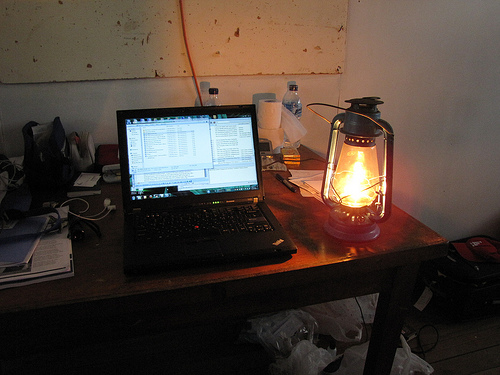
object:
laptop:
[112, 102, 299, 274]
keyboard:
[131, 200, 278, 246]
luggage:
[415, 231, 499, 323]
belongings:
[406, 231, 499, 330]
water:
[282, 83, 303, 152]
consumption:
[280, 84, 304, 151]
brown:
[325, 244, 363, 263]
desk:
[2, 122, 448, 374]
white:
[329, 308, 354, 327]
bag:
[307, 303, 366, 348]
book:
[0, 202, 81, 288]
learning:
[1, 204, 85, 293]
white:
[104, 200, 109, 204]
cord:
[50, 192, 122, 227]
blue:
[57, 125, 65, 142]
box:
[18, 114, 78, 196]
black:
[233, 237, 267, 250]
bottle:
[280, 83, 304, 150]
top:
[288, 84, 300, 92]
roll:
[255, 95, 284, 130]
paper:
[253, 95, 307, 152]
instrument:
[113, 102, 300, 279]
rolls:
[254, 97, 309, 161]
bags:
[238, 277, 445, 374]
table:
[1, 120, 450, 374]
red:
[458, 243, 475, 261]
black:
[466, 272, 484, 285]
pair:
[57, 193, 122, 226]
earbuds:
[54, 194, 120, 223]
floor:
[215, 236, 500, 374]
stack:
[1, 203, 77, 289]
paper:
[0, 199, 82, 293]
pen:
[271, 168, 300, 195]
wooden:
[0, 133, 454, 277]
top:
[112, 103, 271, 211]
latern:
[306, 88, 401, 245]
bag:
[412, 230, 498, 315]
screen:
[122, 115, 266, 201]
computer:
[113, 101, 302, 287]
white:
[13, 13, 208, 48]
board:
[0, 0, 354, 85]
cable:
[56, 194, 119, 224]